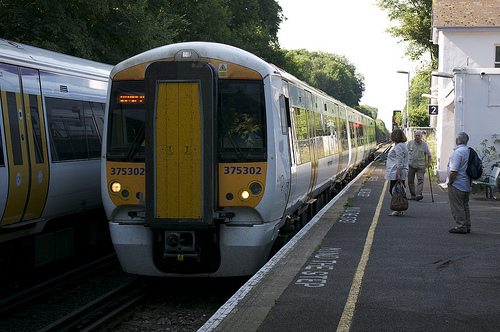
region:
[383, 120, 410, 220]
Woman wearing white shirt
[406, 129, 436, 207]
man walking with cane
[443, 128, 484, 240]
man holding blue backpack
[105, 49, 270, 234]
front of train is orange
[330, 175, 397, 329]
Safety line is painted yellow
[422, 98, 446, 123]
track number is 2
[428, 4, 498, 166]
building next to platform is white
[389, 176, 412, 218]
brown handbag held by lady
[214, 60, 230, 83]
caution sign on front of train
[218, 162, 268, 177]
numbers on front of train are blue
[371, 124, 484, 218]
commuters waiting on train platform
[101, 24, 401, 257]
white and yelow train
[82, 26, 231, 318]
train is on tracks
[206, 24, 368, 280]
train is parked at station platfrorm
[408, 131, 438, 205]
man walking with a cane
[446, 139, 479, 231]
man holding a backpack on shoulder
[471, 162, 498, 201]
empty bench next to building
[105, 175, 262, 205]
train lights are on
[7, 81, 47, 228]
train doors are closed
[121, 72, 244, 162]
tinted front windows on train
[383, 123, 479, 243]
the people standing next to the train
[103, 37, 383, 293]
the yellow and white train sitting on the track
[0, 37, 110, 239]
another yellow and white train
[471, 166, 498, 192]
a bench sitting next to the building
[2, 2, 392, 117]
some trees with green leaves next to the train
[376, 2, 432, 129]
some more trees with green leaves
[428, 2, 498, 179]
the buildings close to the train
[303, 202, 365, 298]
some writing on the ground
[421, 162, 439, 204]
the cane the man is holding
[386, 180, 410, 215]
the bag the person is holding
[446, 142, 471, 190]
a white shirt on a man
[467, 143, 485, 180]
a backpack on a man's back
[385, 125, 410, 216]
a woman holding a backpack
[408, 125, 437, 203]
a man with a cane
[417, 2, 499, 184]
a white building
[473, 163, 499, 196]
abench at a train station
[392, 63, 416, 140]
a light post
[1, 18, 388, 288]
two trains at a station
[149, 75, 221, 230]
a yellow door on a train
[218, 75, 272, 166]
a window on a train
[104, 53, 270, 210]
yellow front of a train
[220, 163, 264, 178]
blue numbers on front of train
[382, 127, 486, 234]
three people standing on platform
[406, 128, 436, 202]
an older man with a cane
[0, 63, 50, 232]
yellow and silver doors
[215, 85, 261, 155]
reflection in front window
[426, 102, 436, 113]
number 2 sign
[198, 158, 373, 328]
white line on edge of platform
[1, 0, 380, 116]
green leafy trees beside train